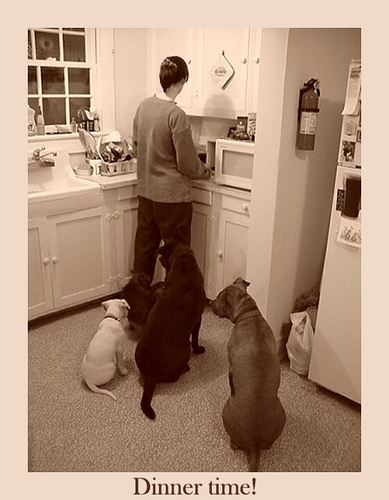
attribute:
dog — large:
[142, 235, 204, 424]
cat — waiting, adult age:
[120, 266, 173, 325]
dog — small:
[82, 296, 131, 402]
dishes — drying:
[100, 133, 133, 162]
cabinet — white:
[200, 30, 246, 121]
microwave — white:
[215, 137, 257, 188]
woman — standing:
[128, 52, 214, 348]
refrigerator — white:
[301, 54, 370, 405]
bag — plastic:
[277, 312, 317, 385]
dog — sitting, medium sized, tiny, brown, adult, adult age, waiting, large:
[203, 278, 287, 476]